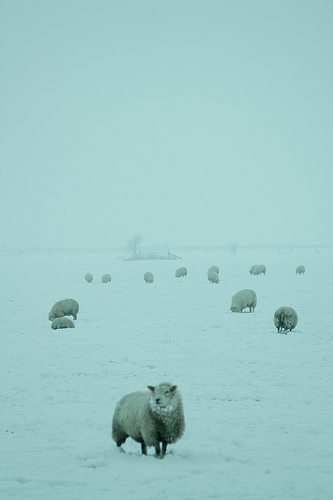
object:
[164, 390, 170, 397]
eye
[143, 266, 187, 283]
sheep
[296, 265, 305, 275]
sheep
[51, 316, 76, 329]
sheep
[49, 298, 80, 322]
sheep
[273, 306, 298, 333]
sheep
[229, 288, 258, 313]
sheep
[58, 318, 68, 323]
wool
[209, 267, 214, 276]
wool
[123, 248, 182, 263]
bridge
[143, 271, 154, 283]
sheep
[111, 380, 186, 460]
sheep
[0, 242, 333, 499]
ground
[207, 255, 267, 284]
sheep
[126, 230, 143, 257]
tree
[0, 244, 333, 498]
snow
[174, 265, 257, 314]
wool sheep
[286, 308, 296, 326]
wool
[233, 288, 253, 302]
wool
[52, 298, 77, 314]
wool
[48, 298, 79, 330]
canadian flag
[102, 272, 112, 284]
sheep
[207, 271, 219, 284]
sheep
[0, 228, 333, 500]
white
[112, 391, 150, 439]
wool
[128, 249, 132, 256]
branch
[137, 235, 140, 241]
branch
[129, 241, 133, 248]
branch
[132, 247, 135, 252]
branch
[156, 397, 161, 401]
nose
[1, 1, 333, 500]
picture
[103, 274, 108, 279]
wool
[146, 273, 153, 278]
wool